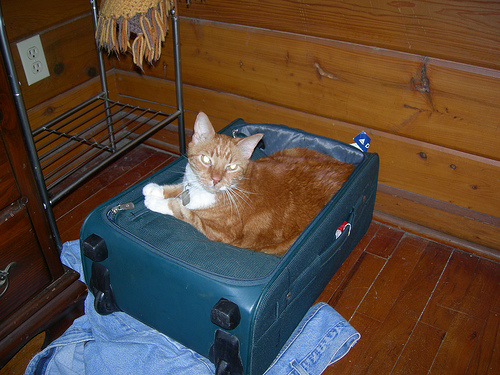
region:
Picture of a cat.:
[20, 43, 455, 373]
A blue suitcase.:
[80, 88, 390, 348]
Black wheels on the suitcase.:
[80, 267, 240, 372]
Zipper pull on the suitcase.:
[103, 193, 140, 218]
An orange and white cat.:
[146, 98, 351, 251]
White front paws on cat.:
[130, 180, 176, 220]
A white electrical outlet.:
[13, 30, 65, 92]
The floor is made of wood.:
[391, 260, 482, 366]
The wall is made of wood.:
[311, 15, 488, 133]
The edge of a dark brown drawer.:
[1, 182, 86, 318]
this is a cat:
[178, 109, 312, 234]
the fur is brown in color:
[260, 178, 304, 217]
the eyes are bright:
[195, 152, 244, 172]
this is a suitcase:
[123, 225, 200, 306]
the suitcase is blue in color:
[143, 235, 179, 301]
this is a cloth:
[312, 307, 333, 353]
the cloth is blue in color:
[299, 307, 319, 357]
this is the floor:
[371, 280, 477, 372]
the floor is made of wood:
[363, 280, 458, 361]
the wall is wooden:
[291, 27, 435, 111]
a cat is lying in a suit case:
[142, 106, 354, 261]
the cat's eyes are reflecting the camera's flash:
[182, 110, 263, 201]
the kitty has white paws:
[140, 176, 171, 216]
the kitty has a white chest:
[175, 161, 215, 211]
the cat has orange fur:
[182, 110, 354, 256]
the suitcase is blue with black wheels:
[75, 116, 381, 366]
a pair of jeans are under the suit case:
[15, 236, 360, 367]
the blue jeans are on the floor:
[21, 236, 356, 372]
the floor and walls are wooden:
[6, 131, 496, 372]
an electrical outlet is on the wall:
[13, 31, 53, 86]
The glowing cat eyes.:
[198, 153, 242, 170]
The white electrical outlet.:
[13, 35, 62, 85]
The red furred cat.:
[141, 112, 352, 253]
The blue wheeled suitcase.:
[77, 223, 273, 373]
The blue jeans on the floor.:
[25, 343, 185, 373]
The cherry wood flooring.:
[364, 252, 497, 374]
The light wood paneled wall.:
[387, 19, 490, 208]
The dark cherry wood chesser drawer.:
[0, 225, 66, 328]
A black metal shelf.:
[48, 97, 140, 171]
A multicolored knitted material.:
[96, 0, 173, 69]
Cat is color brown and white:
[138, 109, 362, 261]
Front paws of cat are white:
[136, 174, 170, 216]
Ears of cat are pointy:
[183, 108, 264, 153]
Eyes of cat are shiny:
[194, 151, 244, 175]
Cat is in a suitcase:
[134, 106, 366, 257]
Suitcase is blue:
[63, 104, 391, 361]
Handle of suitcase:
[304, 219, 360, 271]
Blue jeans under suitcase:
[18, 232, 370, 373]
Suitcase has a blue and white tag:
[341, 124, 377, 156]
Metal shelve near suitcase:
[0, 6, 195, 262]